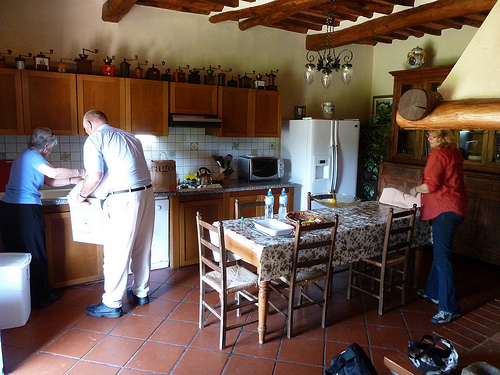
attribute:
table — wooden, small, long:
[209, 199, 436, 343]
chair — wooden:
[194, 211, 259, 351]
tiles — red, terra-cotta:
[1, 251, 499, 374]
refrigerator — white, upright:
[289, 117, 362, 207]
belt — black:
[102, 184, 153, 197]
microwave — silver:
[235, 156, 287, 185]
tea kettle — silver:
[196, 166, 212, 186]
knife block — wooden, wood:
[212, 168, 235, 187]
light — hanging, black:
[304, 18, 354, 89]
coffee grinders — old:
[0, 46, 281, 93]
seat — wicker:
[202, 263, 259, 294]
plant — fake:
[359, 100, 394, 202]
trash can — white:
[1, 250, 33, 333]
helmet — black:
[406, 330, 459, 374]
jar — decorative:
[407, 46, 424, 69]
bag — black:
[326, 343, 380, 375]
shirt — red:
[419, 146, 469, 227]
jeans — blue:
[425, 212, 462, 314]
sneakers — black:
[87, 294, 153, 320]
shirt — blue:
[0, 150, 51, 205]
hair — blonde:
[427, 129, 462, 146]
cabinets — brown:
[0, 70, 282, 140]